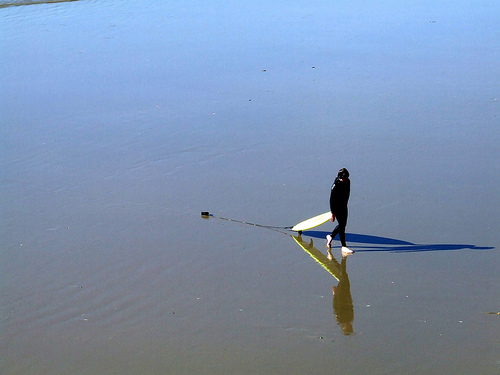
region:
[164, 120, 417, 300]
a person walking in a watered area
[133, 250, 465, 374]
sand is underneath the water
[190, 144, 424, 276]
this person has a surfboad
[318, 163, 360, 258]
the person is wearing a wet suit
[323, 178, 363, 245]
the wet suit is black in color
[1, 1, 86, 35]
a small portion of land is visible in the distance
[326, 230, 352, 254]
the person s barefoot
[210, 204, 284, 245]
a rope trails behind the surfboard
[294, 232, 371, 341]
the persons reflection off of the water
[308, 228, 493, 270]
the person and the surfboards shadow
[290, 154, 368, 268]
surfer dragging surf board in sand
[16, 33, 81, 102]
wet brown sand on beach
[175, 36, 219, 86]
wet brown sand on beach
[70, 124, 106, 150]
wet brown sand on beach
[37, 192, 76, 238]
wet brown sand on beach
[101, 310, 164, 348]
wet brown sand on beach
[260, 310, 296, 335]
wet brown sand on beach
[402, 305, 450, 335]
wet brown sand on beach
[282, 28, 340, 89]
wet brown sand on beach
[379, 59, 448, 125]
wet brown sand on beach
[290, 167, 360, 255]
Person carrying surfboard.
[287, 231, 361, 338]
Reflection on the water.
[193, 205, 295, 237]
black cable attached to surfboard.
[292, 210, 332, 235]
Yellow surfboard on the water.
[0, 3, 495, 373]
Water covering the ground.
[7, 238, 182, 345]
Ripples in the sand under the water.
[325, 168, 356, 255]
Black clothes on the person.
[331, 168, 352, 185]
Dark hair on the person.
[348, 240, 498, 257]
Shadow of the person.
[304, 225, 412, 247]
Shadow from the surfboard.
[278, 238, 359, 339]
reflections in the still water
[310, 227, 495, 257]
shadows cast by the sun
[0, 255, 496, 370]
sand shows through the shallow water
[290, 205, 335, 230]
a white surf board being dragged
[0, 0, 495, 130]
water gets bluer as it gets deeper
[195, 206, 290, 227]
leg strap trailing behind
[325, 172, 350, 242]
a black wet suit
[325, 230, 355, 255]
bare feet on the beach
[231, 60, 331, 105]
bits of floating debris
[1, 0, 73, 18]
edge on the water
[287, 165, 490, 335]
A man, a shadow and a reflection.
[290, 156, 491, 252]
A man holding a surfboard.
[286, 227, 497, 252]
Shadow of the man and board on the sand.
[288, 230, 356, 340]
Reflection of the man and the board on the sand.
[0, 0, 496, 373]
Wet beach sand.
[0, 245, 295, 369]
Water tracks on the sand.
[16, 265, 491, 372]
Small seashells scattered on the sand.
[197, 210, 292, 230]
A rope on the ground behind the surfboard.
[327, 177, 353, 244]
The man is wearing a black wetsuit.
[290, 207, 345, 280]
Surfboard has a white top and a yellow bottom.